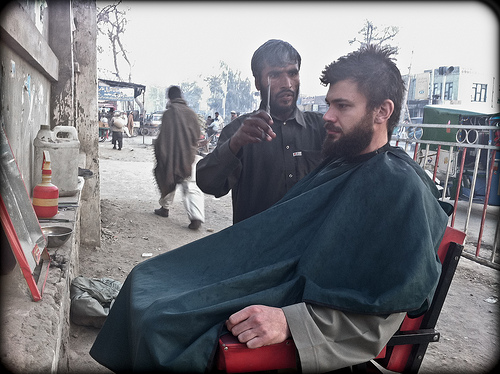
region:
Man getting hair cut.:
[229, 47, 449, 370]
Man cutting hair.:
[194, 37, 334, 219]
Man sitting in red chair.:
[203, 48, 468, 369]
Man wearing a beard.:
[316, 49, 410, 157]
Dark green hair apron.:
[157, 149, 457, 371]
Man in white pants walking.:
[152, 84, 207, 229]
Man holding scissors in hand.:
[227, 82, 285, 164]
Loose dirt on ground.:
[100, 139, 159, 258]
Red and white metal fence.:
[427, 138, 494, 277]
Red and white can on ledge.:
[27, 145, 61, 223]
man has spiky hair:
[327, 44, 396, 119]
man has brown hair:
[317, 50, 408, 144]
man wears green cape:
[97, 131, 462, 345]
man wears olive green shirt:
[304, 306, 441, 364]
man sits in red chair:
[231, 224, 476, 370]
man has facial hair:
[326, 80, 396, 167]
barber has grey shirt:
[215, 98, 338, 213]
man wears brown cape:
[125, 91, 212, 191]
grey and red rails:
[400, 129, 498, 259]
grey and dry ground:
[440, 252, 485, 369]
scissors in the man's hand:
[262, 81, 274, 130]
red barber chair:
[221, 227, 468, 369]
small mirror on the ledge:
[0, 128, 50, 297]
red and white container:
[34, 150, 57, 216]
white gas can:
[33, 124, 83, 195]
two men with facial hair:
[252, 37, 399, 155]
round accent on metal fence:
[456, 129, 477, 144]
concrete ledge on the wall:
[3, 182, 78, 367]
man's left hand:
[231, 305, 292, 348]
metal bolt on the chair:
[430, 334, 440, 339]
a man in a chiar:
[72, 38, 440, 372]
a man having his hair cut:
[132, 51, 491, 341]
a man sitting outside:
[133, 21, 430, 360]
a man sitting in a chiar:
[148, 14, 323, 362]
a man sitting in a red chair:
[96, 51, 374, 351]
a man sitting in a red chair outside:
[149, 72, 461, 362]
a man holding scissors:
[199, 33, 409, 246]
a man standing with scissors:
[189, 14, 419, 321]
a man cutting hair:
[165, 1, 492, 350]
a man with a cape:
[152, 58, 498, 324]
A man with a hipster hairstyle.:
[290, 25, 428, 165]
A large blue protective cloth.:
[89, 142, 461, 371]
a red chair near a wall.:
[213, 220, 473, 371]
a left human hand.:
[210, 298, 300, 366]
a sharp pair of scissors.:
[256, 69, 283, 149]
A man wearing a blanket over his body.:
[147, 75, 212, 233]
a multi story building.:
[418, 57, 498, 203]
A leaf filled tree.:
[197, 56, 257, 127]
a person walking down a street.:
[109, 97, 131, 165]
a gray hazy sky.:
[99, 5, 497, 75]